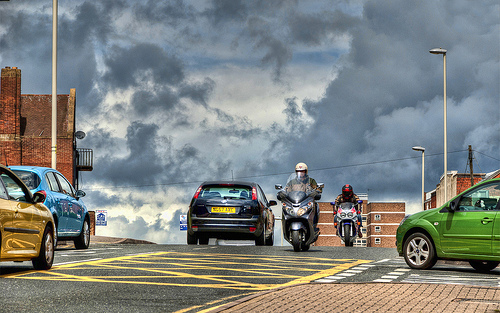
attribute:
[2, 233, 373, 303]
lines — yellow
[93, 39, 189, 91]
cloud — white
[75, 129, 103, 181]
balcony — black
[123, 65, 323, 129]
clouds — white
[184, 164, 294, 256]
vehicle — blue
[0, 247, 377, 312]
street marking — large, yellow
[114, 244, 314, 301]
line — yellow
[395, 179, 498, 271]
car — green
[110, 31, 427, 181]
clouds — white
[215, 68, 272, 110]
clouds — white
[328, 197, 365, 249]
bike — approaching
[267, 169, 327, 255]
bike — approaching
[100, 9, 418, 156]
sky — dark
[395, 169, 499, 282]
vehicle — green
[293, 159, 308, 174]
helmet — white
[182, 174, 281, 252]
car — dark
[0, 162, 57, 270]
vehicle — yellow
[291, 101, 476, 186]
clouds — white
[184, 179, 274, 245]
car — black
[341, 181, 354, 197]
helmet — red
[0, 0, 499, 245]
clouds — white, dark